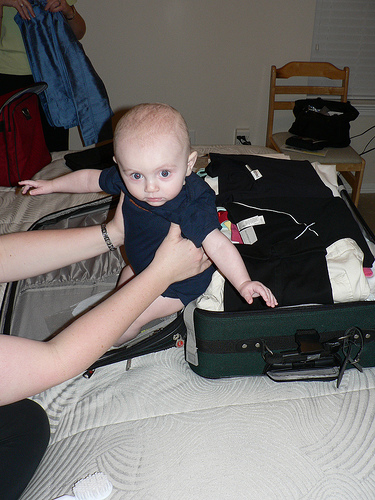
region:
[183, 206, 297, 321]
Hand of a person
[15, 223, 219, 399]
Hand of a person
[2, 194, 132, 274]
Hand of a person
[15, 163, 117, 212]
Hand of a person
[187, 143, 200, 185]
Ear of a person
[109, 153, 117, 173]
Ear of a person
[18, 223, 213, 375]
Hand of an adult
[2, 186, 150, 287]
Hand of an adult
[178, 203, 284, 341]
Hand of a baby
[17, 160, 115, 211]
Hand of a baby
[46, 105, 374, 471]
A parent packing its baby for a trip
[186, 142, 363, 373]
A green suitcase with clothing in it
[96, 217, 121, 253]
A small band on the woman's wrist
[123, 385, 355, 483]
A white bed cloth with spiral patterns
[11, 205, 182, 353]
Shiny silver interior of the suitcase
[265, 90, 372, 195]
A wooden chair with a cushion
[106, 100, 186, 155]
The baby has very short hair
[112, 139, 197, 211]
The baby's face looks very afraid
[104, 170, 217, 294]
A blue shirt on the infant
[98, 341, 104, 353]
A small freckle on the woman's arm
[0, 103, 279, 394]
a woman holding a baby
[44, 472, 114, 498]
a white brush on a bed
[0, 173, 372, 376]
a suitcase on a bed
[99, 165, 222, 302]
baby wearing a blue shirt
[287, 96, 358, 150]
a black bag on a chair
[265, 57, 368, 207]
a wooden chair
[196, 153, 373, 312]
folded clothes in a suitcase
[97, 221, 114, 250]
woman wearing a bracelet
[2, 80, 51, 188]
a red and black bag on a bed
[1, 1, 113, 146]
a person holding a pair of jeans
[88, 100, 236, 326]
The baby is wearing a blue shirt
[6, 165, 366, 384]
The suit case is green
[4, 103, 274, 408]
A person is holding the baby up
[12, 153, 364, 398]
The suit case is on the bed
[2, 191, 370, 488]
The blanket is white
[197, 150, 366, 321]
Clothes inside the suit case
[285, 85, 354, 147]
Black bag on brown chair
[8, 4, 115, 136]
The cloth is blue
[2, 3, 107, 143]
A person is holding the cloth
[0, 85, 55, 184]
The bag is red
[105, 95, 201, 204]
the baby is bald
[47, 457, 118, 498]
this is a toothbrush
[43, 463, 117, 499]
the toothbrush is white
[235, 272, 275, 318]
this is the baby's hand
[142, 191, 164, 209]
this is the baby's mouth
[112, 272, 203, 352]
this is the baby's leg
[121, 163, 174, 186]
these are the baby's eyes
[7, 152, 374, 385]
this is a suitcase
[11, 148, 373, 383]
the suitcase is green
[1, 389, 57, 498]
the person is wearing black pants